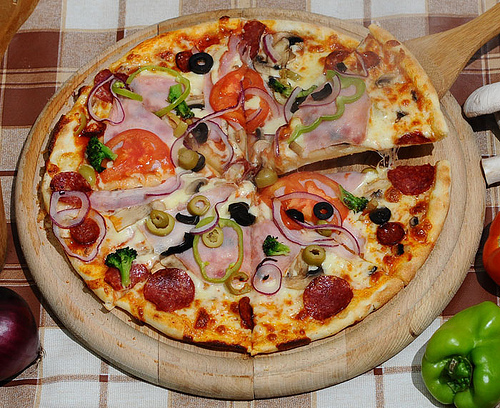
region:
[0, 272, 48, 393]
Red onion on table.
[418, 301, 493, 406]
Green pepper on table.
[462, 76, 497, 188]
Mushrooms on table.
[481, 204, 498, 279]
Tomato on table cloth.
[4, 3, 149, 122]
Brown plaid tablecloth.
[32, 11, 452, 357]
Supreme pizza sitting on table.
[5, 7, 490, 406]
Pizza sitting on cutting board.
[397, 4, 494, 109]
Wooden spatula under pizza slice.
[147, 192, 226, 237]
Green olives on top of pizza.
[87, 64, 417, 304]
Mozzarella cheese on top of pizza.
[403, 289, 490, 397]
a green bell pepper near a pizza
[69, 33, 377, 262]
a pizza with tomatoes on it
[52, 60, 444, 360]
a pizza with melted cheese on it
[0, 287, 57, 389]
a onion near a pizza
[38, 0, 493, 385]
a pizza sitting on table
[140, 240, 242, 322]
pepparoni on a pizza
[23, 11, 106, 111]
a brown and white table cloth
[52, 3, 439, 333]
a pizza with lots of vegetables on it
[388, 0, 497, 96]
a wooden pizza stick for picking up pizza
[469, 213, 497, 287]
a tomatoe near a pizza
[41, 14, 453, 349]
a pizza on a wooden tray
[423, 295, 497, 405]
a green pepper on a table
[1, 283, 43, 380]
a purple onion on a table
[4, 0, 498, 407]
a brown and white checkered tablecloth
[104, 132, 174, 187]
a slice of tomato on a pizza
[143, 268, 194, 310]
a slice of pepperoni on a pizza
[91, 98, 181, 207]
a slice of ham on a pizza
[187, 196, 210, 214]
a slice of green olive on a pizza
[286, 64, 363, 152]
a slice of green pepper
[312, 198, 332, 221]
a slice of black olive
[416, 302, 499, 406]
Green bell pepper next to pizza.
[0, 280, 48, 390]
Red onion by pizza.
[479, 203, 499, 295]
Tomato by pizza.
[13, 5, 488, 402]
Wooden pizza serving dish.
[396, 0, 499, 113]
Wooden spatula.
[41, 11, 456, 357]
Pizza with broccoli, tomato, pepperoni, onions, olive, peppers, ham, and cheese.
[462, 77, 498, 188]
Mushrooms by pizza.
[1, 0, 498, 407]
Brown and white plaid table cloth.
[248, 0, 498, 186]
Slice of pizza being served.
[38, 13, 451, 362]
Pizza with many toppings.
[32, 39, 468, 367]
a pizza with a sorted topping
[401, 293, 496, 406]
green bell pepper net to a pizza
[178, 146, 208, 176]
green and black olive on a pizza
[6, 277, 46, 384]
onion on a plaid table cloth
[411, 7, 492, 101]
brown handle of a wooden board holding pizza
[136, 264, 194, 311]
pepperoni on a large pizza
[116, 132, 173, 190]
tomato on a large pizza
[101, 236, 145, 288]
broccoli on a large pizza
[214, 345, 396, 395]
wooden pizza pan with pizza on it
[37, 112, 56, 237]
burned area of pizza crust